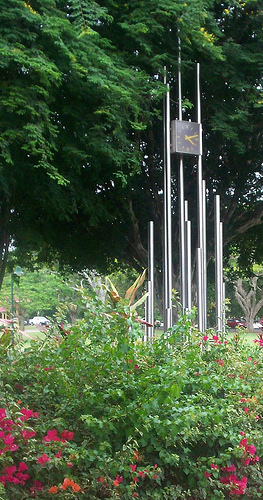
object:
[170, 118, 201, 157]
clock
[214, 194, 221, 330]
poles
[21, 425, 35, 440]
flowers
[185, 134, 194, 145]
hands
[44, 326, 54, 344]
truck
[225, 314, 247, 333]
car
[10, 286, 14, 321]
post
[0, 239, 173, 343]
park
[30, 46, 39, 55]
leaves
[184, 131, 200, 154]
time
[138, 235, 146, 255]
woods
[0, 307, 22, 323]
cars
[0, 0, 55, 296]
tree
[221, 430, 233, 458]
bush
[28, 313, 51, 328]
vehicle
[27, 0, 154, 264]
tree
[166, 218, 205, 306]
threes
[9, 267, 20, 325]
light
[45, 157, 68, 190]
branches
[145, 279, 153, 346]
pipe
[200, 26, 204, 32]
flowers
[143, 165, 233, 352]
chime